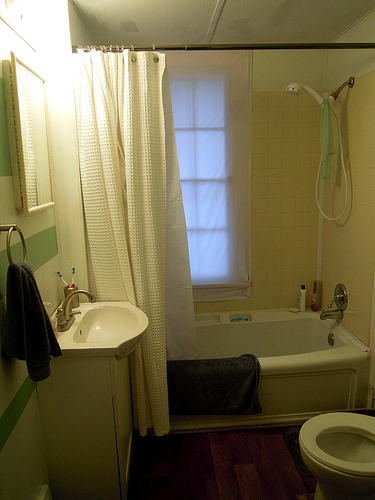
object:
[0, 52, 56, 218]
cabinet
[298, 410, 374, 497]
toilet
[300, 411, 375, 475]
seat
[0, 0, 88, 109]
light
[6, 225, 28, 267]
rack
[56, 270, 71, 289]
toothbrushes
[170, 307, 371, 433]
bath tub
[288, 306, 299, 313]
soap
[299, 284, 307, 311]
bottle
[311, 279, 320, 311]
bottle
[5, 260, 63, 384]
towel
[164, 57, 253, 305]
curtains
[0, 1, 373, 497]
bathroom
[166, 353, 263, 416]
bath towel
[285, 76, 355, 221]
shower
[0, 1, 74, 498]
wall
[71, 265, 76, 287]
toothbrushes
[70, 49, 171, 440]
curtain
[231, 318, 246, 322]
handle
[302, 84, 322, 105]
handle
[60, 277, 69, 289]
handle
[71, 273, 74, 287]
handle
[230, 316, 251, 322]
razor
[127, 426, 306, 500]
floors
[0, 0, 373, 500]
scene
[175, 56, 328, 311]
wall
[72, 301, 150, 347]
sink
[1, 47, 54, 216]
medicine cabinet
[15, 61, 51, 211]
mirror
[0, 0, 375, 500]
area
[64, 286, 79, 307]
glass